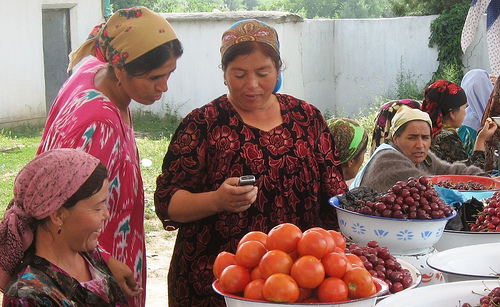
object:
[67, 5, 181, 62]
headband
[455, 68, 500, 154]
woman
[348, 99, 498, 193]
woman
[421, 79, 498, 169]
woman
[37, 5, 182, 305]
woman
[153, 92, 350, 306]
dress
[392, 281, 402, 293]
grapes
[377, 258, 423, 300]
bowl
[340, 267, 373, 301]
tomatoes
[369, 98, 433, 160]
bandana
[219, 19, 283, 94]
bandana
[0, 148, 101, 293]
bandana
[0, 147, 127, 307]
woman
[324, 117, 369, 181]
woman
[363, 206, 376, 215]
fruits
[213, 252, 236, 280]
vegetables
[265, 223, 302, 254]
tomato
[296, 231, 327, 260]
tomato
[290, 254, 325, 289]
tomato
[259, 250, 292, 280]
tomato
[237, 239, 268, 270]
tomato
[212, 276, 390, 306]
bowl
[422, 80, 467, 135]
headband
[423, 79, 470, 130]
head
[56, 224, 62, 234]
earring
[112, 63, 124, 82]
ear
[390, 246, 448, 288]
bowls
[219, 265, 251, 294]
fruit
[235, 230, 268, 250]
vegetable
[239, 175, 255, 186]
black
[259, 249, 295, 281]
tomatoes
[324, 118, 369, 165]
head band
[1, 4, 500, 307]
market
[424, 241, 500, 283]
bowl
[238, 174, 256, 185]
phone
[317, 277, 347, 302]
tomatoes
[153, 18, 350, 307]
woman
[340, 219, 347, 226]
designs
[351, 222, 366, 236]
designs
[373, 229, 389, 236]
designs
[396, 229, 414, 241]
designs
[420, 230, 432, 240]
designs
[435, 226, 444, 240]
designs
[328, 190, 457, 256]
bowl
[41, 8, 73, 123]
door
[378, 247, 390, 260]
grapes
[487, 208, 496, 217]
grapes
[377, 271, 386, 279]
grapes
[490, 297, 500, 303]
grapes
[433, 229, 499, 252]
bowls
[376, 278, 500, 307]
bowls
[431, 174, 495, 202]
bowls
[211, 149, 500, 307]
table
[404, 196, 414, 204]
grapes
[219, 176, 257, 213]
hand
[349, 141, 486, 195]
sweater